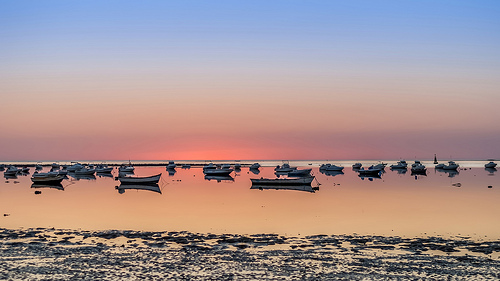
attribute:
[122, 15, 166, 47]
sky — clear, blue, red, purple, orange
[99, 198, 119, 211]
beach — sandy, calm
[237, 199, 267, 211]
water — calm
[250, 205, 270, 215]
ocean — calm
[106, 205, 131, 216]
sand — gray, wet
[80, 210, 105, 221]
surface — calm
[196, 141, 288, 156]
sun — setting